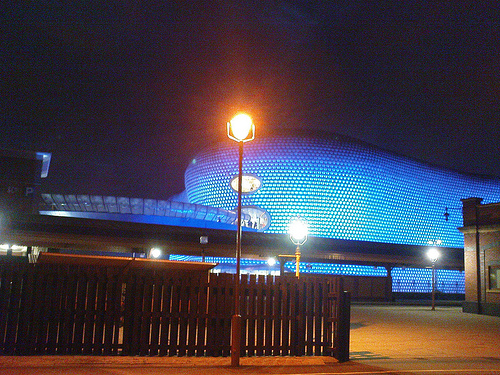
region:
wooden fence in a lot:
[2, 253, 347, 360]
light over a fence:
[224, 105, 257, 148]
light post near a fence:
[233, 140, 243, 372]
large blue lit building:
[186, 112, 499, 304]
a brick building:
[453, 194, 499, 329]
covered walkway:
[5, 211, 465, 313]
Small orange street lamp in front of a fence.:
[221, 109, 255, 364]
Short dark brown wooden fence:
[0, 260, 351, 360]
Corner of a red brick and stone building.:
[460, 195, 495, 315]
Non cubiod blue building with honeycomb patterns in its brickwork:
[165, 125, 495, 300]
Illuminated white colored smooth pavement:
[0, 290, 495, 370]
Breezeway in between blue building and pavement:
[0, 210, 467, 273]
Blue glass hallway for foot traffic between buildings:
[37, 191, 270, 228]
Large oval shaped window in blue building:
[227, 171, 260, 191]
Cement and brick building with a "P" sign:
[0, 150, 53, 273]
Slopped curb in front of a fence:
[0, 355, 340, 366]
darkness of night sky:
[0, 2, 498, 203]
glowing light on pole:
[225, 112, 254, 365]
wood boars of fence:
[2, 263, 344, 353]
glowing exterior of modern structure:
[2, 127, 497, 298]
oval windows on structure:
[229, 173, 270, 230]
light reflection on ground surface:
[345, 304, 496, 374]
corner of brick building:
[458, 196, 498, 314]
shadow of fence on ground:
[347, 348, 388, 362]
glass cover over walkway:
[41, 192, 266, 232]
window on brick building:
[485, 260, 498, 293]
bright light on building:
[190, 157, 206, 172]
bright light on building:
[275, 130, 295, 152]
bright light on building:
[309, 139, 340, 169]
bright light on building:
[366, 156, 389, 175]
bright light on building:
[411, 162, 426, 180]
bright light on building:
[406, 179, 421, 204]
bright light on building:
[366, 206, 396, 225]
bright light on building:
[306, 201, 342, 238]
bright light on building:
[254, 242, 285, 272]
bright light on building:
[411, 277, 434, 294]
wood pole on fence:
[70, 258, 91, 362]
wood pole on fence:
[88, 262, 105, 366]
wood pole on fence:
[127, 257, 144, 359]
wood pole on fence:
[155, 264, 177, 355]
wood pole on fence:
[185, 268, 211, 366]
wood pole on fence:
[213, 270, 233, 354]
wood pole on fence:
[253, 270, 274, 347]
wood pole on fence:
[304, 276, 329, 355]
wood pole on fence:
[333, 272, 353, 362]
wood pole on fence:
[268, 266, 283, 348]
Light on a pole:
[213, 98, 262, 374]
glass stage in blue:
[33, 156, 237, 231]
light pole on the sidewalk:
[410, 220, 445, 314]